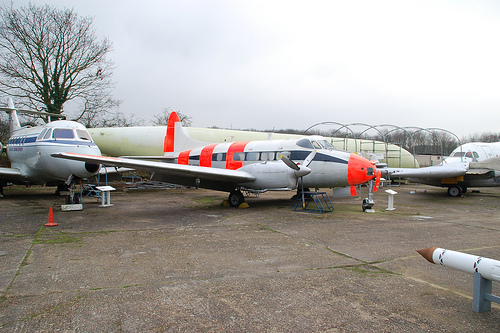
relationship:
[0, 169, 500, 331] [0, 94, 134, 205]
ground below airplane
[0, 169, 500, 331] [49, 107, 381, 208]
ground below airplane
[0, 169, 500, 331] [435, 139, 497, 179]
ground below airplane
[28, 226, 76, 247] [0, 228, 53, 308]
grass between cracks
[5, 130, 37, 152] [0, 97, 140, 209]
blue stripe on airplane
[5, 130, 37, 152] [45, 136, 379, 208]
blue stripe on plane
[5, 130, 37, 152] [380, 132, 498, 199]
blue stripe on plane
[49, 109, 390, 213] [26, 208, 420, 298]
airplane on pavement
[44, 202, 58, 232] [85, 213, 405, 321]
cone on ground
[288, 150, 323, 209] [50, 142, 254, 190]
propeller on wing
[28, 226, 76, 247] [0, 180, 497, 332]
grass on pavement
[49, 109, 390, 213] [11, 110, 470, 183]
airplane behind gate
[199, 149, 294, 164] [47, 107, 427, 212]
windows on plane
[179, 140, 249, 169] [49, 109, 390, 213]
orange stripes on airplane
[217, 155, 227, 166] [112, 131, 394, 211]
window on plane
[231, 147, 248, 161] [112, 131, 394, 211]
window on plane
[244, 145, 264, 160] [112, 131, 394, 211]
window on plane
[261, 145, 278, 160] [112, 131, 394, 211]
window on plane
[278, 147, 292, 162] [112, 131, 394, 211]
window on plane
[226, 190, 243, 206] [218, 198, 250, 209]
landing wheel by blocks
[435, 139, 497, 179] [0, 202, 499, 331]
airplane on ground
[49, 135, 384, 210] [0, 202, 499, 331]
airplane on ground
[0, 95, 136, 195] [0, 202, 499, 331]
airplane on ground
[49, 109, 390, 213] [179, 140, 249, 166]
airplane has orange stripes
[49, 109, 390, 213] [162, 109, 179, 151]
airplane has orange stripes